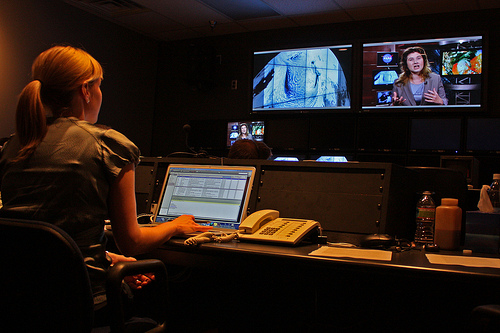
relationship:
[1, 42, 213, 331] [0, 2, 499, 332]
person sitting inside building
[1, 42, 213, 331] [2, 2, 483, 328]
person sitting inside building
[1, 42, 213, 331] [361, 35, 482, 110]
person watching tv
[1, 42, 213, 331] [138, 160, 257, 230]
person using laptop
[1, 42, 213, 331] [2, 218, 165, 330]
person sitting in chair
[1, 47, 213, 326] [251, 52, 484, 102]
person looking screen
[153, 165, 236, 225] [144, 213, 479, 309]
monitor on desk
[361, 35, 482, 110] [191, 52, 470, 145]
tv on wall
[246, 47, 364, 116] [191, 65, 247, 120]
tv on wall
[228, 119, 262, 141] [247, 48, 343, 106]
monitor by tv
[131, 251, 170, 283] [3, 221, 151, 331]
arm on chair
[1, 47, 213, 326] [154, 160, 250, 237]
person with laptop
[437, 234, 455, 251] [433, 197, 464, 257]
liquid in bottle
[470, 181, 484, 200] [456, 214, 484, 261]
tissue in box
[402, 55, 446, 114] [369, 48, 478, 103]
woman on screen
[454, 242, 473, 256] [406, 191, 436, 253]
cap on bottle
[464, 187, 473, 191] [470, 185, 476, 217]
cap on bottle